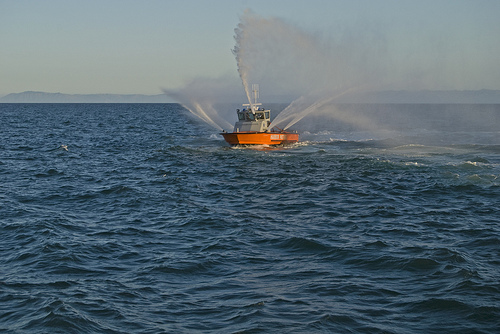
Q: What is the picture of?
A: A boat.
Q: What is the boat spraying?
A: Water.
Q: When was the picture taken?
A: Daytime.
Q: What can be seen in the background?
A: Mountains.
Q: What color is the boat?
A: Orange.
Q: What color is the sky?
A: Blue.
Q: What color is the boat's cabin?
A: White.